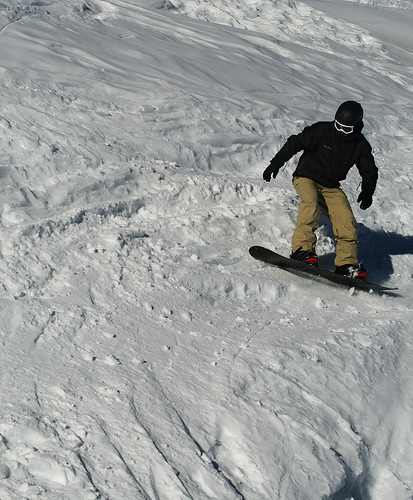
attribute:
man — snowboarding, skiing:
[263, 100, 378, 280]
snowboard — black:
[249, 246, 399, 294]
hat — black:
[336, 100, 363, 124]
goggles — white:
[334, 120, 354, 135]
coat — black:
[270, 122, 379, 196]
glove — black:
[263, 164, 280, 182]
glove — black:
[356, 191, 374, 210]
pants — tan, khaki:
[291, 175, 360, 266]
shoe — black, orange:
[291, 251, 318, 266]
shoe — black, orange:
[335, 265, 368, 279]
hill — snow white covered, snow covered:
[0, 0, 413, 500]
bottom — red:
[303, 256, 318, 265]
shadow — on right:
[317, 210, 412, 284]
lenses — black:
[336, 123, 351, 132]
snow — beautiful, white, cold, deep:
[0, 0, 413, 500]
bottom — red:
[357, 272, 369, 280]